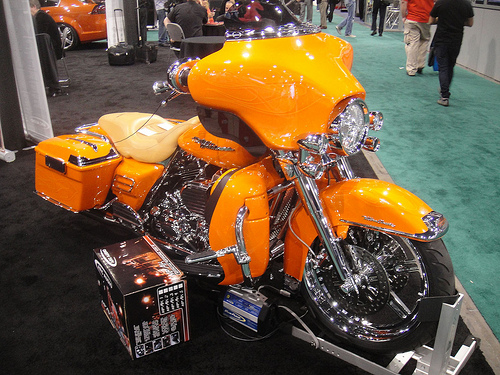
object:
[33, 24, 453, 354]
motorcycle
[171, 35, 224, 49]
tablecloth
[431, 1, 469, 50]
shirt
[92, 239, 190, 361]
box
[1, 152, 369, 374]
floor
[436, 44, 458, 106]
pants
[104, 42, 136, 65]
bag